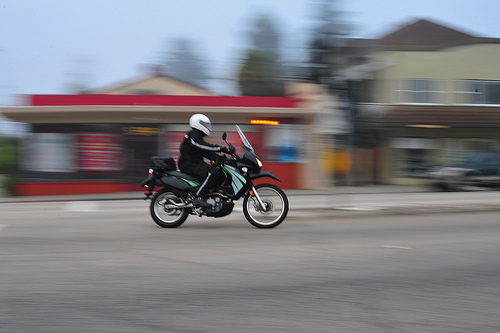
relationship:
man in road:
[177, 113, 229, 208] [7, 191, 496, 328]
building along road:
[5, 72, 325, 186] [4, 207, 497, 327]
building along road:
[320, 12, 497, 188] [4, 207, 497, 327]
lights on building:
[238, 115, 282, 130] [7, 58, 325, 194]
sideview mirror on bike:
[221, 131, 229, 146] [139, 123, 289, 225]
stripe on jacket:
[190, 137, 222, 153] [177, 127, 218, 167]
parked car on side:
[423, 165, 498, 190] [0, 182, 499, 212]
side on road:
[0, 182, 499, 212] [4, 207, 497, 327]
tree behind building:
[235, 9, 292, 101] [5, 20, 499, 192]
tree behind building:
[308, 2, 356, 86] [5, 20, 499, 192]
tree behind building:
[158, 35, 211, 89] [5, 20, 499, 192]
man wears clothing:
[177, 113, 229, 208] [176, 127, 221, 200]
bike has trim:
[139, 125, 289, 229] [220, 160, 249, 201]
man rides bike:
[175, 111, 229, 212] [139, 125, 289, 229]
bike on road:
[139, 125, 289, 229] [7, 191, 496, 328]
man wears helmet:
[177, 113, 229, 208] [188, 112, 214, 137]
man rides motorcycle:
[177, 113, 229, 208] [149, 152, 292, 231]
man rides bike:
[177, 113, 229, 208] [146, 159, 296, 232]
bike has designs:
[146, 159, 296, 232] [223, 163, 245, 201]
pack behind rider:
[118, 133, 186, 188] [177, 109, 230, 211]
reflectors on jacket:
[197, 112, 216, 132] [176, 130, 218, 190]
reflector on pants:
[195, 172, 214, 194] [182, 157, 234, 205]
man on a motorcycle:
[177, 113, 229, 208] [141, 150, 286, 222]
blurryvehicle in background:
[426, 160, 492, 192] [363, 116, 479, 209]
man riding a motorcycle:
[177, 113, 229, 208] [150, 161, 290, 228]